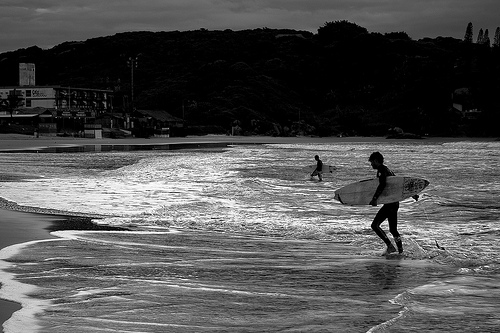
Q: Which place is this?
A: It is a beach.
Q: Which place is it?
A: It is a beach.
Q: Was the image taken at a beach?
A: Yes, it was taken in a beach.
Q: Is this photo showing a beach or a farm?
A: It is showing a beach.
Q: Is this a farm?
A: No, it is a beach.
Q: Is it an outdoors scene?
A: Yes, it is outdoors.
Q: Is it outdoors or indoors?
A: It is outdoors.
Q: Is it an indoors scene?
A: No, it is outdoors.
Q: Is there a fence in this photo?
A: No, there are no fences.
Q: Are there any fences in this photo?
A: No, there are no fences.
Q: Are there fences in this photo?
A: No, there are no fences.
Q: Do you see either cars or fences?
A: No, there are no fences or cars.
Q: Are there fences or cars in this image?
A: No, there are no fences or cars.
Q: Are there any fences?
A: No, there are no fences.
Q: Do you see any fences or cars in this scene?
A: No, there are no fences or cars.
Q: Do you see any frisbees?
A: No, there are no frisbees.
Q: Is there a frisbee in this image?
A: No, there are no frisbees.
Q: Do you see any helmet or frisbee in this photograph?
A: No, there are no frisbees or helmets.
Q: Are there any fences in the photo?
A: No, there are no fences.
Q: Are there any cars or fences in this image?
A: No, there are no fences or cars.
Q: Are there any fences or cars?
A: No, there are no fences or cars.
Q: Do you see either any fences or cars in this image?
A: No, there are no fences or cars.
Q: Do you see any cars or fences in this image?
A: No, there are no fences or cars.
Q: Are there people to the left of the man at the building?
A: Yes, there are people to the left of the man.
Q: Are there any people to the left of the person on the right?
A: Yes, there are people to the left of the man.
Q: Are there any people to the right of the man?
A: No, the people are to the left of the man.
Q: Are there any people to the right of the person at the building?
A: No, the people are to the left of the man.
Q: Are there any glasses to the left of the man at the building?
A: No, there are people to the left of the man.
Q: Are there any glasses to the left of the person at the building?
A: No, there are people to the left of the man.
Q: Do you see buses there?
A: No, there are no buses.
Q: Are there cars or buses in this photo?
A: No, there are no buses or cars.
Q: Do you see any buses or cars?
A: No, there are no buses or cars.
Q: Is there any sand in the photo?
A: Yes, there is sand.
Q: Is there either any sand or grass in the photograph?
A: Yes, there is sand.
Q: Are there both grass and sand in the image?
A: No, there is sand but no grass.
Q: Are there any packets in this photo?
A: No, there are no packets.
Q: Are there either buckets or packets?
A: No, there are no packets or buckets.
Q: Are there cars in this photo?
A: No, there are no cars.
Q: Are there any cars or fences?
A: No, there are no cars or fences.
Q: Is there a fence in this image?
A: No, there are no fences.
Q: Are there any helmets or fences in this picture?
A: No, there are no fences or helmets.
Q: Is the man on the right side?
A: Yes, the man is on the right of the image.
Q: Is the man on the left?
A: No, the man is on the right of the image.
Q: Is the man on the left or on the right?
A: The man is on the right of the image.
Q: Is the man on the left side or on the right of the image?
A: The man is on the right of the image.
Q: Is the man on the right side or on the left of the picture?
A: The man is on the right of the image.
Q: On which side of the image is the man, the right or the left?
A: The man is on the right of the image.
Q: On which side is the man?
A: The man is on the right of the image.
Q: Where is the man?
A: The man is at the building.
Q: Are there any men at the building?
A: Yes, there is a man at the building.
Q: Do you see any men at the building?
A: Yes, there is a man at the building.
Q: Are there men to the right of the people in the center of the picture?
A: Yes, there is a man to the right of the people.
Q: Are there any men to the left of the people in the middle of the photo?
A: No, the man is to the right of the people.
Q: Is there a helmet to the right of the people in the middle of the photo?
A: No, there is a man to the right of the people.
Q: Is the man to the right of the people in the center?
A: Yes, the man is to the right of the people.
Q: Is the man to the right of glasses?
A: No, the man is to the right of the people.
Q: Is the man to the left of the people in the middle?
A: No, the man is to the right of the people.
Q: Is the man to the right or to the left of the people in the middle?
A: The man is to the right of the people.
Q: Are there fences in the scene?
A: No, there are no fences.